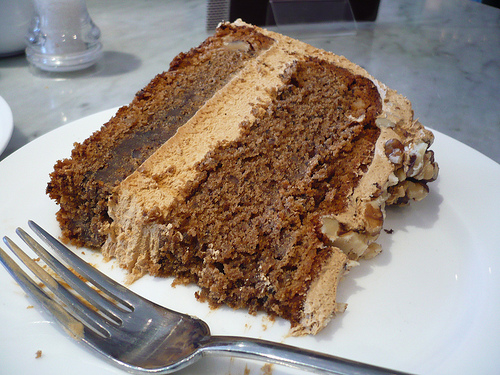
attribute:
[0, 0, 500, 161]
table — marble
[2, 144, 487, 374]
plate — white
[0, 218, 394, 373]
fork — stainless steel, white , smudges 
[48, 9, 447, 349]
cake — sliced, brown and light brown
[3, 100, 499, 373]
saucer — white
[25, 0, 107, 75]
salt shaker — clear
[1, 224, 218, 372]
fork — silver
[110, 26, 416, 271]
piece cake — tan and brown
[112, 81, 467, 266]
cake — sliced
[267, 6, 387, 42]
document holder — clear, plastic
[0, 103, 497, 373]
plate — white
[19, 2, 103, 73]
object — glass